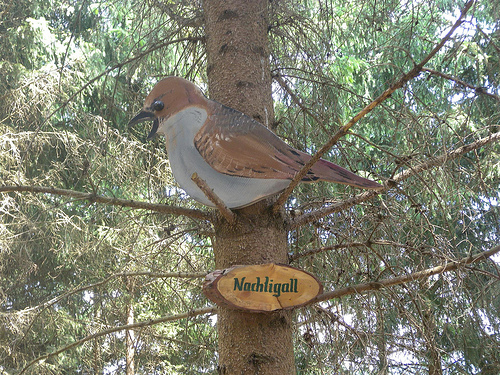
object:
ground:
[368, 135, 390, 186]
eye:
[151, 99, 164, 114]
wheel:
[126, 76, 390, 230]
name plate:
[209, 265, 319, 310]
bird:
[127, 76, 385, 220]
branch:
[40, 58, 122, 128]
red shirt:
[361, 135, 474, 206]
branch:
[17, 307, 220, 374]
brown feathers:
[194, 104, 383, 189]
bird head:
[126, 75, 202, 140]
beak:
[127, 108, 158, 140]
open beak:
[126, 110, 158, 140]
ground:
[304, 70, 326, 111]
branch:
[272, 1, 472, 211]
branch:
[293, 128, 498, 228]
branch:
[322, 241, 500, 303]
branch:
[0, 184, 213, 218]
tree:
[1, 2, 498, 372]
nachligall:
[234, 272, 298, 298]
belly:
[177, 158, 281, 208]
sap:
[244, 350, 267, 364]